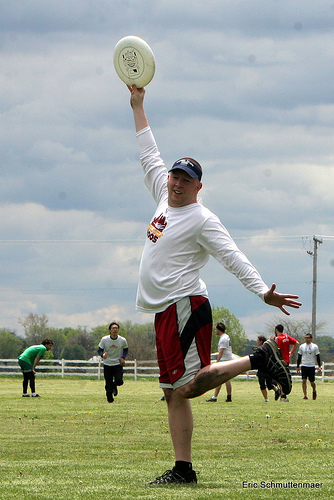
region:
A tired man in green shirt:
[12, 329, 64, 400]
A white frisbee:
[105, 27, 180, 90]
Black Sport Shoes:
[148, 464, 214, 489]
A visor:
[168, 153, 216, 180]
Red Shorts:
[140, 304, 230, 374]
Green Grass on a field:
[22, 413, 126, 478]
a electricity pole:
[293, 213, 333, 331]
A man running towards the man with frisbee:
[82, 310, 138, 399]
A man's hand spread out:
[262, 275, 305, 317]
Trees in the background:
[14, 308, 82, 339]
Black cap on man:
[160, 149, 213, 187]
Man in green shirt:
[16, 332, 57, 401]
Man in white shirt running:
[97, 316, 132, 405]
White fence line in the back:
[0, 354, 333, 389]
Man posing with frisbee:
[108, 34, 246, 421]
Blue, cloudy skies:
[19, 37, 332, 307]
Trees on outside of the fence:
[6, 318, 232, 373]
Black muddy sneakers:
[244, 330, 300, 407]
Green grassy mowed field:
[5, 316, 332, 493]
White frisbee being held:
[93, 31, 178, 109]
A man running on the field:
[95, 318, 135, 404]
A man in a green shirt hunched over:
[12, 331, 73, 401]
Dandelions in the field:
[260, 409, 325, 450]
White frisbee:
[108, 30, 162, 88]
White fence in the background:
[56, 357, 102, 378]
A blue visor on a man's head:
[167, 156, 205, 177]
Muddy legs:
[141, 353, 291, 485]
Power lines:
[267, 230, 333, 335]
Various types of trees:
[53, 325, 90, 361]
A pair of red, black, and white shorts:
[150, 291, 212, 398]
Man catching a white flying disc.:
[95, 30, 290, 429]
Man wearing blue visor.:
[131, 147, 229, 217]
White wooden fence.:
[1, 344, 332, 396]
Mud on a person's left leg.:
[133, 344, 290, 487]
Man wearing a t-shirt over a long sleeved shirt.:
[82, 318, 140, 403]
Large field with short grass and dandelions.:
[1, 370, 332, 495]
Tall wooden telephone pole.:
[279, 225, 332, 331]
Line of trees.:
[16, 314, 322, 387]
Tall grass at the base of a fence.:
[1, 371, 332, 392]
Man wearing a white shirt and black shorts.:
[299, 328, 321, 405]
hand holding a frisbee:
[105, 33, 166, 95]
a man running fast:
[85, 320, 138, 407]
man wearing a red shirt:
[271, 319, 294, 353]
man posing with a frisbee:
[113, 35, 280, 478]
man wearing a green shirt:
[8, 332, 51, 365]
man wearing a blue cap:
[160, 155, 209, 209]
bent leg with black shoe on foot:
[138, 348, 300, 403]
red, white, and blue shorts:
[151, 289, 215, 391]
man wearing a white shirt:
[297, 334, 328, 369]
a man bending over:
[12, 330, 56, 402]